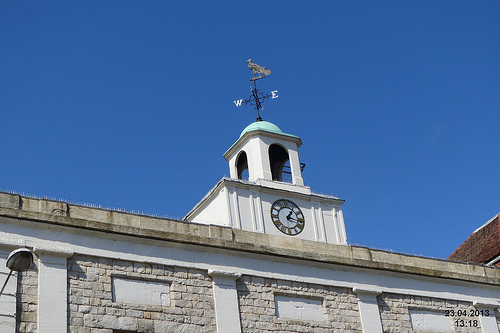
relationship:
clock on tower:
[271, 197, 304, 235] [180, 58, 351, 244]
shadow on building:
[26, 227, 114, 292] [15, 91, 469, 331]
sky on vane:
[2, 6, 492, 263] [231, 57, 280, 122]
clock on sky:
[264, 196, 312, 238] [40, 51, 425, 317]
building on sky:
[15, 91, 469, 331] [18, 13, 207, 196]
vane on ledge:
[231, 57, 280, 122] [1, 190, 499, 288]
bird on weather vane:
[242, 56, 269, 75] [228, 58, 280, 120]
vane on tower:
[231, 57, 280, 122] [179, 118, 349, 245]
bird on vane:
[246, 59, 272, 78] [231, 57, 280, 122]